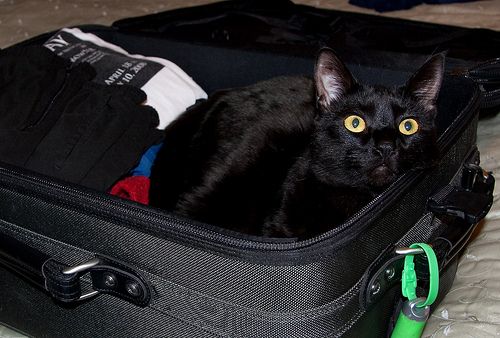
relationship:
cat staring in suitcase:
[119, 54, 450, 246] [12, 5, 483, 323]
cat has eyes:
[148, 47, 449, 238] [334, 111, 424, 140]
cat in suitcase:
[148, 47, 449, 238] [12, 5, 483, 323]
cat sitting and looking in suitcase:
[148, 47, 449, 238] [12, 5, 483, 323]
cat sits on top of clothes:
[148, 47, 449, 238] [10, 59, 189, 153]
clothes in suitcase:
[10, 59, 189, 153] [12, 5, 483, 323]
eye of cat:
[395, 117, 417, 137] [148, 47, 449, 238]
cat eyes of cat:
[344, 115, 367, 135] [148, 47, 449, 238]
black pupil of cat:
[352, 118, 359, 127] [148, 47, 449, 238]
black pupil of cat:
[404, 120, 411, 130] [148, 47, 449, 238]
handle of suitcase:
[5, 216, 158, 315] [12, 5, 483, 323]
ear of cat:
[399, 44, 445, 110] [149, 33, 499, 258]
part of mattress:
[479, 263, 491, 281] [2, 0, 498, 337]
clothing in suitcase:
[109, 173, 150, 204] [76, 11, 480, 329]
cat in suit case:
[148, 47, 449, 238] [8, 21, 488, 330]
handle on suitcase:
[5, 216, 158, 315] [12, 5, 483, 323]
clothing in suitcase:
[18, 29, 189, 184] [12, 5, 483, 323]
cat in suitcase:
[148, 47, 449, 238] [0, 175, 332, 337]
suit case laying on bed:
[0, 0, 498, 338] [373, 10, 485, 337]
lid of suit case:
[109, 0, 499, 120] [0, 0, 498, 338]